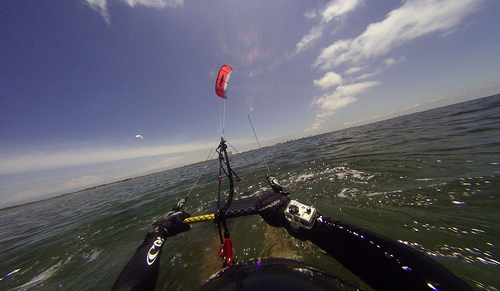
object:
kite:
[214, 63, 236, 100]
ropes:
[172, 96, 228, 209]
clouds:
[277, 0, 500, 132]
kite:
[134, 133, 145, 141]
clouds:
[84, 0, 191, 30]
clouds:
[2, 130, 285, 210]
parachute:
[162, 61, 295, 217]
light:
[213, 18, 286, 113]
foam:
[307, 165, 371, 201]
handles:
[149, 192, 293, 233]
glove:
[252, 191, 294, 228]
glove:
[146, 210, 195, 236]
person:
[110, 192, 481, 291]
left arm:
[113, 227, 168, 291]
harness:
[144, 235, 167, 269]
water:
[0, 91, 500, 291]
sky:
[0, 0, 500, 208]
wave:
[0, 148, 500, 291]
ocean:
[0, 93, 500, 290]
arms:
[316, 217, 483, 291]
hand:
[146, 210, 193, 236]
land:
[0, 175, 137, 210]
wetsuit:
[105, 191, 469, 291]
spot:
[219, 74, 224, 88]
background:
[1, 166, 162, 219]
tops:
[293, 163, 378, 185]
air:
[0, 0, 500, 123]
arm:
[107, 233, 170, 291]